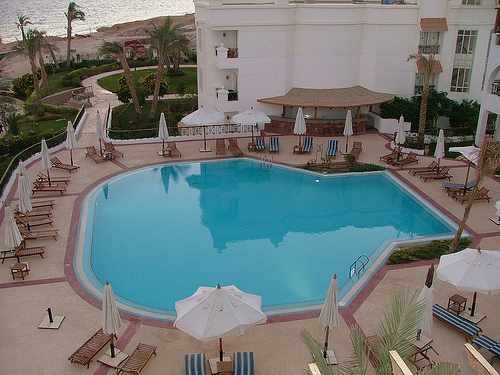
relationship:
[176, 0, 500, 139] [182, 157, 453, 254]
building over reflection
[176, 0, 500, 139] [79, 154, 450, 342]
building over pool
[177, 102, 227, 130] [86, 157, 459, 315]
umbrella surrounding pool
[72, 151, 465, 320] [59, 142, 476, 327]
water in swimming pool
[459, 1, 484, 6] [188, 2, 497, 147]
windows on building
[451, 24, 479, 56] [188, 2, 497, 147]
windows on building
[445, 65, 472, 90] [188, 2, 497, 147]
windows on building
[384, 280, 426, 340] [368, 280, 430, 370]
leaves on tree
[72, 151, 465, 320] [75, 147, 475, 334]
water in pool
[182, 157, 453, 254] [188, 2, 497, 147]
reflection of building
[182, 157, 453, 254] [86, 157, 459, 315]
reflection in pool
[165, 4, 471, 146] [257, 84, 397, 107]
building with awning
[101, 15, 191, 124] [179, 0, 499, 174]
palm trees next to building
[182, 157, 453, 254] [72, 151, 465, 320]
reflection in water